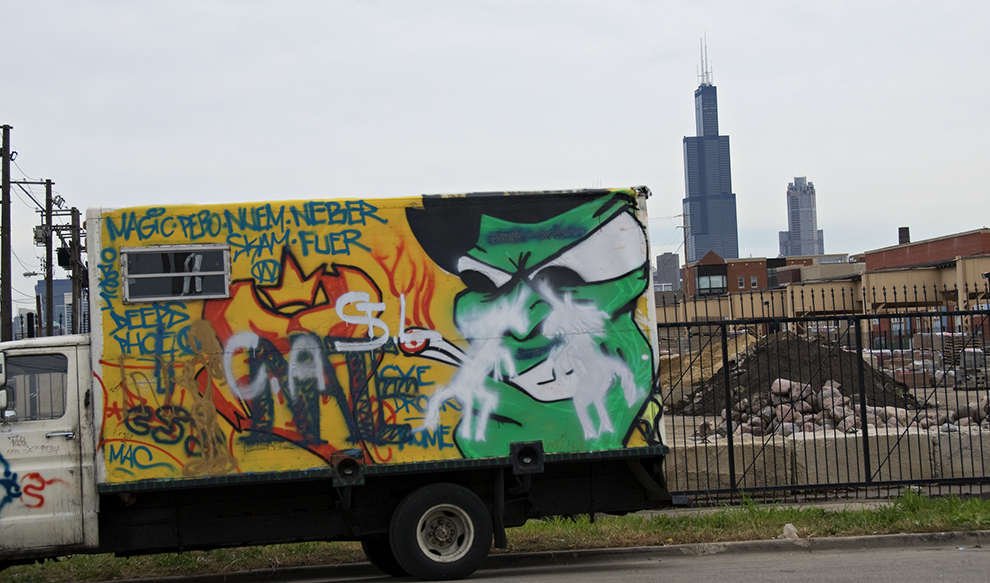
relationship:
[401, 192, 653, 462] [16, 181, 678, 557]
face painted on a truck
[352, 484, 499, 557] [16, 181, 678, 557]
wheels on a truck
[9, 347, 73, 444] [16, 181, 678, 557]
window of a truck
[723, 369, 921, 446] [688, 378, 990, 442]
pile of rocks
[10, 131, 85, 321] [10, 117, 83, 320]
row of poles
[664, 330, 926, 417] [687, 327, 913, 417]
dirt of dirt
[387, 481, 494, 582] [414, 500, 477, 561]
tire with rim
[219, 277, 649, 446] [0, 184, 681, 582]
paint on side of truck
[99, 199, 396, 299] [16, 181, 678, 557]
letters on side of truck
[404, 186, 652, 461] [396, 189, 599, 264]
face with hair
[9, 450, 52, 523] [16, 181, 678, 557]
writing on front of truck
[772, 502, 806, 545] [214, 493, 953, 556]
trash on ground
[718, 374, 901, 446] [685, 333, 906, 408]
rocks in dirt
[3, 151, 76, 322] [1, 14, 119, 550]
poles on side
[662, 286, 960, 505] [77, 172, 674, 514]
fence near trailer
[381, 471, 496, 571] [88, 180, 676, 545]
tire on trailer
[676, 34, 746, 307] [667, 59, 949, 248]
tower in distance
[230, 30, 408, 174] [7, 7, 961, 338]
clouds in sky